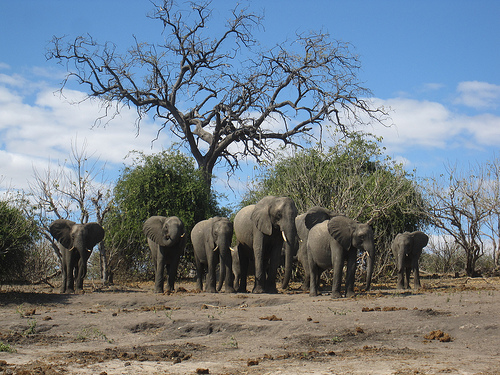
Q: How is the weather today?
A: It is cloudy.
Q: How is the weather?
A: It is cloudy.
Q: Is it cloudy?
A: Yes, it is cloudy.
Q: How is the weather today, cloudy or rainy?
A: It is cloudy.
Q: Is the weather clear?
A: No, it is cloudy.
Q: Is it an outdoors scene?
A: Yes, it is outdoors.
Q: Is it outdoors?
A: Yes, it is outdoors.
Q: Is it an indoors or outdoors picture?
A: It is outdoors.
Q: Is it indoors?
A: No, it is outdoors.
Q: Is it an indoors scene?
A: No, it is outdoors.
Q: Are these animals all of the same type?
A: Yes, all the animals are elephants.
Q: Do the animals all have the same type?
A: Yes, all the animals are elephants.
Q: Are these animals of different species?
A: No, all the animals are elephants.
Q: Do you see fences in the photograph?
A: No, there are no fences.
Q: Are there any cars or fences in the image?
A: No, there are no fences or cars.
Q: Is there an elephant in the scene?
A: Yes, there is an elephant.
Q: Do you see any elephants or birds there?
A: Yes, there is an elephant.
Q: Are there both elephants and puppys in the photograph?
A: No, there is an elephant but no puppys.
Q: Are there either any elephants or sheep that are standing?
A: Yes, the elephant is standing.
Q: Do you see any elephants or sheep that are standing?
A: Yes, the elephant is standing.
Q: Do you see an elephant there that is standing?
A: Yes, there is an elephant that is standing.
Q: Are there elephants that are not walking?
A: Yes, there is an elephant that is standing.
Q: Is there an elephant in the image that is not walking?
A: Yes, there is an elephant that is standing.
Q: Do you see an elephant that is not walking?
A: Yes, there is an elephant that is standing .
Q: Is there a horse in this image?
A: No, there are no horses.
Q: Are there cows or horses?
A: No, there are no horses or cows.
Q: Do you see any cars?
A: No, there are no cars.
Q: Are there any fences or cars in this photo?
A: No, there are no cars or fences.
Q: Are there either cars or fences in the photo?
A: No, there are no cars or fences.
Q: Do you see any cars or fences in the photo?
A: No, there are no cars or fences.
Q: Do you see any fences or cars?
A: No, there are no cars or fences.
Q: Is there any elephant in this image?
A: Yes, there are elephants.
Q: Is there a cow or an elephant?
A: Yes, there are elephants.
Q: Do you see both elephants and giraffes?
A: No, there are elephants but no giraffes.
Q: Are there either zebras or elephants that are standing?
A: Yes, the elephants are standing.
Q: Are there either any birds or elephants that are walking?
A: Yes, the elephants are walking.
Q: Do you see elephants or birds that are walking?
A: Yes, the elephants are walking.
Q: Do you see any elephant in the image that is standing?
A: Yes, there are elephants that are standing.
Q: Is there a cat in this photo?
A: No, there are no cats.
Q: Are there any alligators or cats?
A: No, there are no cats or alligators.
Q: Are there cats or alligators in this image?
A: No, there are no cats or alligators.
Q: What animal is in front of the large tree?
A: The elephants are in front of the tree.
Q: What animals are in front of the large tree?
A: The animals are elephants.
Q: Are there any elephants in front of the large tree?
A: Yes, there are elephants in front of the tree.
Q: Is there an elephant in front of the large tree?
A: Yes, there are elephants in front of the tree.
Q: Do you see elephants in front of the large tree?
A: Yes, there are elephants in front of the tree.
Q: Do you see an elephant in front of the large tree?
A: Yes, there are elephants in front of the tree.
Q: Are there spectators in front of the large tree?
A: No, there are elephants in front of the tree.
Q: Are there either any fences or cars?
A: No, there are no cars or fences.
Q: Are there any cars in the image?
A: No, there are no cars.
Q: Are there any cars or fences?
A: No, there are no cars or fences.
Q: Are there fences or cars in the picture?
A: No, there are no cars or fences.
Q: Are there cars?
A: No, there are no cars.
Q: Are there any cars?
A: No, there are no cars.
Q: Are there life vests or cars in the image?
A: No, there are no cars or life vests.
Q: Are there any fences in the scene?
A: No, there are no fences.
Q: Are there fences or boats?
A: No, there are no fences or boats.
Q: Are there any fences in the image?
A: No, there are no fences.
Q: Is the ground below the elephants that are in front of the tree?
A: Yes, the ground is below the elephants.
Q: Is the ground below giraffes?
A: No, the ground is below the elephants.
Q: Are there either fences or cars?
A: No, there are no fences or cars.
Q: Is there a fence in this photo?
A: No, there are no fences.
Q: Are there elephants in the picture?
A: Yes, there is an elephant.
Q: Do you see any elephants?
A: Yes, there is an elephant.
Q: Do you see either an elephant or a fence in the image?
A: Yes, there is an elephant.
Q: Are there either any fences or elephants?
A: Yes, there is an elephant.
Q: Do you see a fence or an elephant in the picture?
A: Yes, there is an elephant.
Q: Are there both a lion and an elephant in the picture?
A: No, there is an elephant but no lions.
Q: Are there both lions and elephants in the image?
A: No, there is an elephant but no lions.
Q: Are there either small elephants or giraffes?
A: Yes, there is a small elephant.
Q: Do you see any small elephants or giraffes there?
A: Yes, there is a small elephant.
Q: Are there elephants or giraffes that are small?
A: Yes, the elephant is small.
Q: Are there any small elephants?
A: Yes, there is a small elephant.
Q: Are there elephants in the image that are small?
A: Yes, there is an elephant that is small.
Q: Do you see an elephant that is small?
A: Yes, there is an elephant that is small.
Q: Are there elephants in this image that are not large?
A: Yes, there is a small elephant.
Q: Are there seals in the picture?
A: No, there are no seals.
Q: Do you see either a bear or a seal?
A: No, there are no seals or bears.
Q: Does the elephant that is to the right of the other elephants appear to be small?
A: Yes, the elephant is small.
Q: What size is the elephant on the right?
A: The elephant is small.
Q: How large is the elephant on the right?
A: The elephant is small.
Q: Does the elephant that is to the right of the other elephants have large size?
A: No, the elephant is small.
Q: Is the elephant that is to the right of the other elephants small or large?
A: The elephant is small.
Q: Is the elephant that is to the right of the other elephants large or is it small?
A: The elephant is small.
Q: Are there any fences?
A: No, there are no fences.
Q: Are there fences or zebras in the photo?
A: No, there are no fences or zebras.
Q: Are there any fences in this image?
A: No, there are no fences.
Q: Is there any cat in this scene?
A: No, there are no cats.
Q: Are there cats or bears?
A: No, there are no cats or bears.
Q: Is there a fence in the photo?
A: No, there are no fences.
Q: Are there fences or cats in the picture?
A: No, there are no fences or cats.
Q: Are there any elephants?
A: Yes, there is an elephant.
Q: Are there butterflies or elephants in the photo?
A: Yes, there is an elephant.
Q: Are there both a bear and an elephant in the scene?
A: No, there is an elephant but no bears.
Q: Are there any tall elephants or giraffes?
A: Yes, there is a tall elephant.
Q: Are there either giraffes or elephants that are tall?
A: Yes, the elephant is tall.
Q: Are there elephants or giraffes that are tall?
A: Yes, the elephant is tall.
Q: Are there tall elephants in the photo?
A: Yes, there is a tall elephant.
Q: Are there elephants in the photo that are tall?
A: Yes, there is an elephant that is tall.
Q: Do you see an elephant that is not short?
A: Yes, there is a tall elephant.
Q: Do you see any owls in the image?
A: No, there are no owls.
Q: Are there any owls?
A: No, there are no owls.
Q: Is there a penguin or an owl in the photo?
A: No, there are no owls or penguins.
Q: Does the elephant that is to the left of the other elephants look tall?
A: Yes, the elephant is tall.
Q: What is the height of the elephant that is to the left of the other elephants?
A: The elephant is tall.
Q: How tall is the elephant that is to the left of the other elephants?
A: The elephant is tall.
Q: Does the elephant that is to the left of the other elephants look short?
A: No, the elephant is tall.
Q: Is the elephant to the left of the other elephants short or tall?
A: The elephant is tall.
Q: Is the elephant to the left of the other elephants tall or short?
A: The elephant is tall.